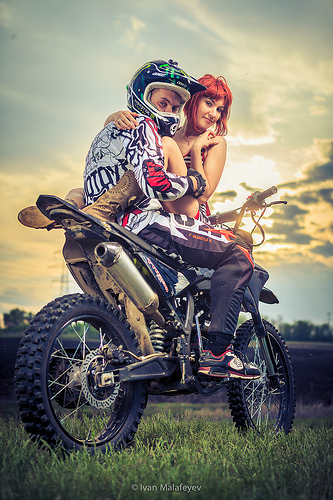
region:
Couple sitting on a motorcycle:
[6, 36, 314, 464]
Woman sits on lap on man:
[17, 39, 241, 278]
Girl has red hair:
[172, 52, 240, 159]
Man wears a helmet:
[75, 41, 261, 386]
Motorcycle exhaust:
[87, 234, 172, 336]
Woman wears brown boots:
[13, 51, 237, 242]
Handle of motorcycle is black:
[245, 179, 284, 205]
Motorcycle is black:
[7, 227, 300, 472]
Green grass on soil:
[3, 402, 328, 499]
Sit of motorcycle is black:
[22, 189, 184, 285]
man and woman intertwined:
[24, 47, 264, 262]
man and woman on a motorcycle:
[57, 45, 272, 384]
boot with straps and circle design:
[15, 157, 145, 236]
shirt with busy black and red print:
[76, 101, 192, 228]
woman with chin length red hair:
[178, 52, 230, 142]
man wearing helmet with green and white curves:
[118, 49, 200, 140]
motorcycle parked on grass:
[12, 301, 304, 467]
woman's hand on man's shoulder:
[88, 48, 188, 148]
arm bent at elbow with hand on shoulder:
[177, 116, 230, 200]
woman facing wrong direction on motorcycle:
[55, 53, 278, 371]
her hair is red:
[187, 59, 241, 147]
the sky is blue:
[26, 25, 97, 134]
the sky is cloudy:
[16, 15, 325, 220]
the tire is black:
[16, 283, 151, 453]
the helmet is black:
[113, 45, 205, 147]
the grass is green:
[163, 413, 282, 488]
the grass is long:
[167, 421, 229, 499]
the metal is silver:
[90, 236, 170, 320]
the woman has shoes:
[14, 185, 126, 257]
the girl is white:
[166, 53, 252, 230]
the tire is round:
[16, 271, 148, 466]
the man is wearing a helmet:
[117, 42, 191, 145]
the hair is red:
[190, 72, 235, 145]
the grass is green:
[169, 416, 219, 475]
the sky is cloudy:
[120, 7, 297, 68]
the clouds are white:
[201, 8, 304, 101]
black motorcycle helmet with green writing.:
[134, 60, 188, 93]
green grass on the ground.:
[148, 446, 243, 471]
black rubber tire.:
[18, 321, 48, 427]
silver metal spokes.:
[65, 333, 98, 419]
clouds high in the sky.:
[288, 159, 324, 257]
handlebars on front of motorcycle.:
[225, 184, 283, 225]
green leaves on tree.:
[6, 300, 28, 328]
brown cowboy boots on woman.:
[96, 185, 134, 220]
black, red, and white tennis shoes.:
[205, 359, 259, 376]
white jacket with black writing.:
[90, 137, 112, 182]